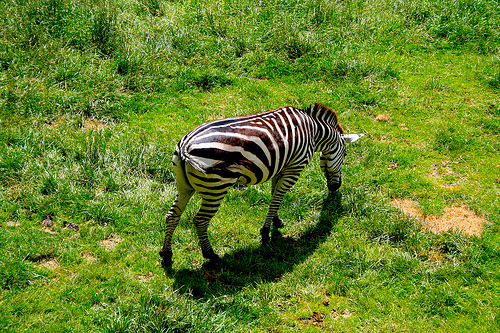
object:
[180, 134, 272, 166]
stripe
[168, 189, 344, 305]
shadow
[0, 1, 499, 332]
ground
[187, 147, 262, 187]
stripe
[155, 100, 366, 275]
zebra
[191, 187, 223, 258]
leg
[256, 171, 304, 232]
leg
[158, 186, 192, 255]
leg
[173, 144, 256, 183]
tail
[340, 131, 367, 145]
ear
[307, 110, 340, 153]
neck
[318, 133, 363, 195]
head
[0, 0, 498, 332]
grass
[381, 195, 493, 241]
patch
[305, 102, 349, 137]
hair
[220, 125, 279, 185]
stripes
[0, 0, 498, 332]
field